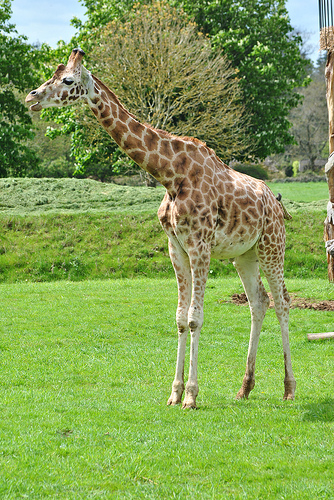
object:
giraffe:
[23, 49, 295, 408]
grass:
[0, 275, 334, 500]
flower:
[137, 48, 141, 52]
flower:
[235, 67, 237, 69]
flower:
[163, 11, 167, 14]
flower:
[198, 32, 201, 34]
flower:
[135, 1, 139, 5]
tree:
[74, 1, 252, 189]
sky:
[0, 0, 320, 76]